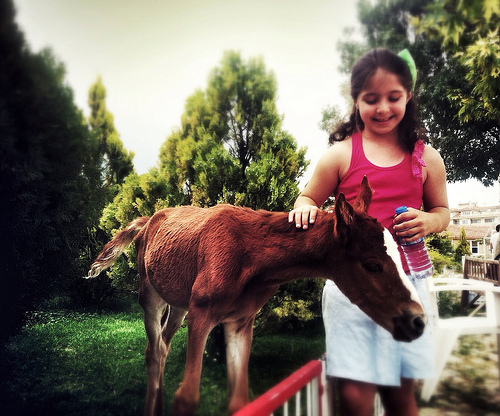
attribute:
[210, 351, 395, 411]
fence — red, white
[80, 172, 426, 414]
horse — young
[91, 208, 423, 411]
pony — brown and white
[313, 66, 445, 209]
girl tank — pink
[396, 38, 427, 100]
bow — green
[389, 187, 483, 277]
bottle — clear, blue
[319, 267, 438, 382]
skirt — white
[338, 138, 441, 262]
tank top — pink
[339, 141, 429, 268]
top — pink, tank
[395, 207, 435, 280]
water bottle — plastic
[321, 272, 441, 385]
shorts — white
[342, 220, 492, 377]
shorts — white